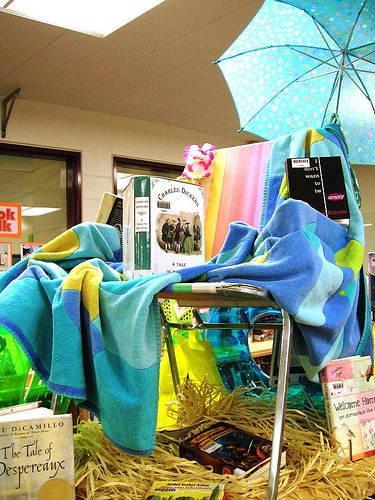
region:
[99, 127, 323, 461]
a small beach chair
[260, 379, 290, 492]
the leg of a beach chair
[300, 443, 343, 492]
a bunch of yellow straw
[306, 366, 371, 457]
the cover of a pink book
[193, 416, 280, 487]
the black cover of a book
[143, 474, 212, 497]
the yellow cover of a book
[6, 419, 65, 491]
a tan cover of a book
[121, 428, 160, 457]
the corner of a towel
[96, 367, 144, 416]
the blue part of a towel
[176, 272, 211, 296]
the fabric of a chair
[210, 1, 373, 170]
An open umbrella.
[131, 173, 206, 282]
A Charles Dickens book.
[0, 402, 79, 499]
Hardback copy of The Tale of Despereaux.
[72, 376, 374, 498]
A pile of straw with some books laying in it.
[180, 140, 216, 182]
A flowered lei.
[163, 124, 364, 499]
A chair with metal legs.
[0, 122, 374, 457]
A blue and green beach towel.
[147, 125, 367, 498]
A chair with a striped back.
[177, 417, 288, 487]
A book laying atop some straw.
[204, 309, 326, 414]
A blown up innertube.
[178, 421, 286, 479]
the book is laying down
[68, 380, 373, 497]
a pile of straw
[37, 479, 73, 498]
gold sticker on the book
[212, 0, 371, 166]
a blue umbrella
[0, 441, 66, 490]
the title of a book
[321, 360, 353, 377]
pink square on the book cover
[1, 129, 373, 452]
a blue beach towel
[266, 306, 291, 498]
metal chair leg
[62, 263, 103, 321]
a yellow patch on the towel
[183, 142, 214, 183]
a flower necklace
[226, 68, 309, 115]
polka dot pattern on umbrella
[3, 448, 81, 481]
tile of the book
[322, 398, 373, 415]
title of the book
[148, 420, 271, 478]
book in the pile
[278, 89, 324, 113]
the umbrella is blue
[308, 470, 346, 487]
hay on the display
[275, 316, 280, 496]
pole of the chair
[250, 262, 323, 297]
the towel is blue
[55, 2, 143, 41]
light on the ceiling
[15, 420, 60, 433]
author of the book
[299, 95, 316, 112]
the umbrella is blue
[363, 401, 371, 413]
the book is pink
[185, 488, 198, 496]
the book is yellow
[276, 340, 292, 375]
the leg is silver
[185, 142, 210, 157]
the flower is purple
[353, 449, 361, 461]
the book is orange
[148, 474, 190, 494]
the book is laying down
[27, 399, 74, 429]
the book is open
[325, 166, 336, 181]
the book is black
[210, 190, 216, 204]
the chair is yellow